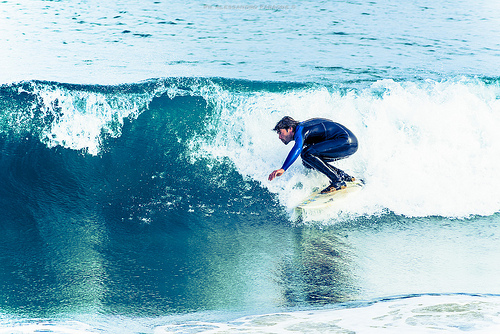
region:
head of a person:
[270, 100, 308, 142]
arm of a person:
[283, 128, 316, 175]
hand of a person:
[254, 161, 286, 187]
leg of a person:
[298, 148, 345, 180]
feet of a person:
[312, 182, 348, 210]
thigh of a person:
[312, 134, 357, 173]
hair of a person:
[276, 112, 304, 126]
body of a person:
[302, 116, 348, 153]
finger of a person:
[263, 172, 276, 180]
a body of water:
[34, 11, 330, 102]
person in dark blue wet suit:
[268, 115, 360, 195]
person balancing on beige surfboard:
[267, 114, 367, 210]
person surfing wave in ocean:
[1, 77, 498, 224]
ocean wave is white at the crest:
[2, 74, 498, 222]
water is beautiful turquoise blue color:
[0, 2, 497, 333]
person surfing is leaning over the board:
[267, 114, 369, 212]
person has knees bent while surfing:
[295, 142, 323, 169]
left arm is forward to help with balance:
[267, 124, 307, 183]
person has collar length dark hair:
[272, 116, 299, 132]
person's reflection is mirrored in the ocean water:
[277, 209, 355, 308]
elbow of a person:
[288, 142, 310, 153]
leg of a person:
[310, 162, 338, 178]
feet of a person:
[323, 177, 348, 193]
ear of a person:
[285, 121, 302, 133]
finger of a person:
[260, 170, 282, 181]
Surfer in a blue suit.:
[264, 117, 366, 201]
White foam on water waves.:
[374, 105, 494, 203]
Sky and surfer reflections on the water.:
[100, 249, 469, 281]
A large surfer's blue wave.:
[0, 74, 257, 206]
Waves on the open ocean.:
[125, 11, 476, 51]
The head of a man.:
[271, 114, 298, 146]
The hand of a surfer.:
[269, 164, 285, 184]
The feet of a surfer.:
[316, 169, 358, 198]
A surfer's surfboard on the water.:
[289, 172, 389, 215]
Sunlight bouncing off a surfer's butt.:
[329, 124, 365, 159]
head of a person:
[268, 113, 295, 148]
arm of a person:
[280, 134, 315, 166]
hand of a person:
[268, 167, 285, 175]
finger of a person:
[268, 167, 283, 178]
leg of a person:
[306, 155, 339, 190]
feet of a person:
[316, 181, 346, 196]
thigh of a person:
[309, 134, 360, 169]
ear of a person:
[282, 119, 297, 136]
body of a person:
[276, 110, 380, 153]